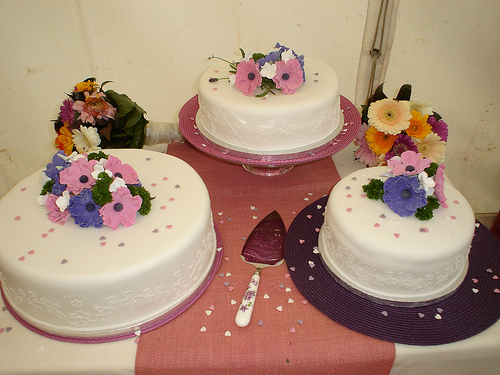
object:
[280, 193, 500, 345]
mat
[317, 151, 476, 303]
cake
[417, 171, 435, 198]
flowers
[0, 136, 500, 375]
table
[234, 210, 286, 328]
spatula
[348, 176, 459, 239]
sprinkles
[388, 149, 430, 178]
flower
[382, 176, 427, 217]
flower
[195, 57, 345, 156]
cake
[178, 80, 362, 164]
plate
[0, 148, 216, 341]
cake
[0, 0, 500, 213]
wall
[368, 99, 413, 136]
flowers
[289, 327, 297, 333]
confetti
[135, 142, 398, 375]
runner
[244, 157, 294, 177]
stand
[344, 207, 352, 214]
fondant